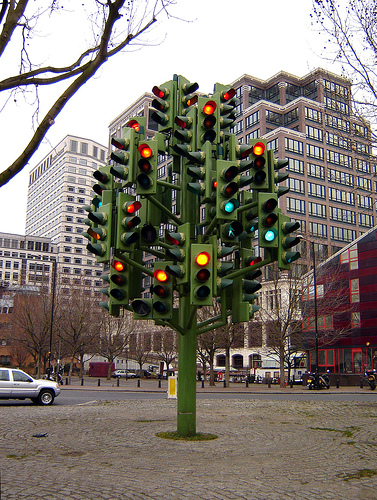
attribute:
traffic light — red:
[134, 140, 158, 192]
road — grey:
[0, 380, 375, 406]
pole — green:
[163, 329, 209, 445]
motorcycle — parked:
[304, 365, 333, 390]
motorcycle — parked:
[303, 366, 320, 389]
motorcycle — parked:
[361, 364, 376, 390]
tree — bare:
[9, 282, 117, 376]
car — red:
[69, 358, 150, 405]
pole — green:
[94, 164, 263, 398]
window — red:
[318, 349, 323, 366]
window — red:
[328, 346, 334, 364]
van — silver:
[1, 362, 72, 413]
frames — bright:
[315, 345, 365, 369]